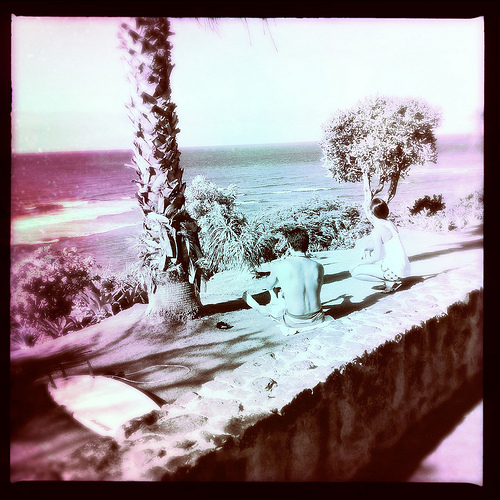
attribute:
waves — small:
[11, 193, 141, 242]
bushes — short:
[183, 164, 365, 277]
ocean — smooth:
[12, 147, 483, 324]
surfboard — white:
[39, 354, 160, 441]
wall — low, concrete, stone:
[11, 261, 484, 481]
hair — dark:
[286, 227, 311, 252]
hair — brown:
[369, 196, 390, 220]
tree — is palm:
[183, 172, 271, 283]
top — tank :
[364, 204, 420, 272]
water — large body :
[44, 150, 134, 220]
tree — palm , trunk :
[123, 169, 208, 325]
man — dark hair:
[249, 222, 323, 327]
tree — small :
[320, 80, 455, 248]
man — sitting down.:
[225, 216, 324, 329]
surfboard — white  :
[45, 366, 163, 439]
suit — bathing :
[366, 220, 405, 288]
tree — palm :
[97, 14, 225, 334]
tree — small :
[317, 84, 445, 227]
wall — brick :
[284, 327, 420, 410]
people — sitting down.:
[255, 191, 409, 320]